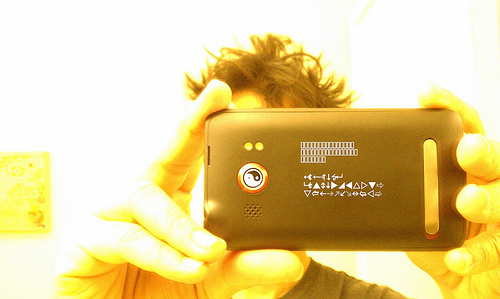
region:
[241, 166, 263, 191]
Black and white ying yang symbol.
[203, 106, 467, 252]
A black phone with a ying yang symbol.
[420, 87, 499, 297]
A man's left hand.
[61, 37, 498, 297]
A dark haired man holding a phone.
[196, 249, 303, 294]
A right hand thumb.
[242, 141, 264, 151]
Two small yellow circles above a Ying Yang.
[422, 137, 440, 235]
A long rectangle silver strip down the back of a phone.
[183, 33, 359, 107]
Shaggy brown hair on a head.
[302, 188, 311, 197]
A hollow upside down triangle on the bottom row of shapes.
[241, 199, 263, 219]
Several blots dots under the ying yang symbol for sound to come through the phone.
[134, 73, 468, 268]
Person holding a cellphone in the mirror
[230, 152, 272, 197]
camera on the cellphone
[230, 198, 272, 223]
speaker on the cellphone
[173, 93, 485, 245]
Person holding a cellphone in the mirror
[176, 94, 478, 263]
Person holding a cellphone in the mirror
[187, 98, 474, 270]
Person holding a cellphone in the mirror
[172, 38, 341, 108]
man with black hair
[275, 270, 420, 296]
man wearing a black tee shirt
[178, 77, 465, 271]
Person holding a cellphone in the mirror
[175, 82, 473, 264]
Person holding a cellphone in the mirror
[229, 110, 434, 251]
this is a phone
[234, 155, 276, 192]
this is the camera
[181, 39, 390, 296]
this is a man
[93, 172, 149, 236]
the man is light skinned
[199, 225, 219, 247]
this is the nail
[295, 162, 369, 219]
this is a writing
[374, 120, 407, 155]
the phone is black in color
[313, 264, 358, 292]
this is a t shirt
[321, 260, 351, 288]
the t shirt is black in color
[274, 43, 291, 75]
this is the hair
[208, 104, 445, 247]
this is a cell phone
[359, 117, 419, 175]
it is black in color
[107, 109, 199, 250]
these are the fingers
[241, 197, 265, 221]
this is the ear piece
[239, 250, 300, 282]
this is the thumb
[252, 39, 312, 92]
these are the hair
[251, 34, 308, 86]
the hair is long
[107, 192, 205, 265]
these are two fingers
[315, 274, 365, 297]
this is the t shirt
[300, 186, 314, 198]
white symbol on cell phone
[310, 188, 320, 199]
white symbol on cell phone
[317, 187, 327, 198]
white symbol on cell phone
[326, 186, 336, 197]
white symbol on cell phone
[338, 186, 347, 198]
white symbol on cell phone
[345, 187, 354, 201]
white symbol on cell phone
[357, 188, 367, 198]
white symbol on cell phone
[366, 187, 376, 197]
white symbol on cell phone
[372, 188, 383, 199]
white symbol on cell phone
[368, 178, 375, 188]
white symbol on cell phone